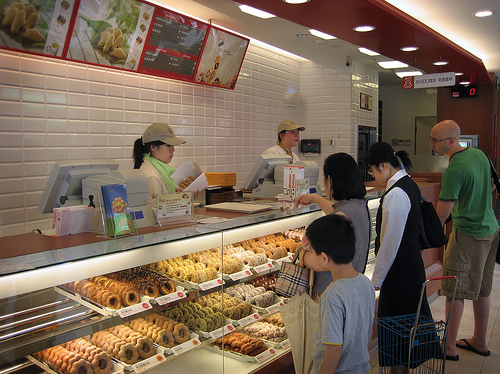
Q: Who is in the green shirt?
A: A man.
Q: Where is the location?
A: Bakery.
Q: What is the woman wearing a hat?
A: Employee.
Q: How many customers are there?
A: Four.